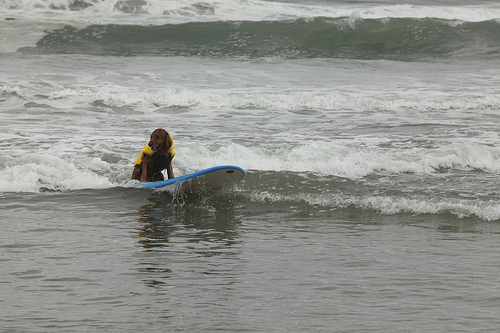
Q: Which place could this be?
A: It is an ocean.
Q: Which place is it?
A: It is an ocean.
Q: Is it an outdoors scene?
A: Yes, it is outdoors.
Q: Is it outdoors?
A: Yes, it is outdoors.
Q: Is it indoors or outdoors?
A: It is outdoors.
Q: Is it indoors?
A: No, it is outdoors.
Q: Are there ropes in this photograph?
A: No, there are no ropes.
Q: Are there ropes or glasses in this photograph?
A: No, there are no ropes or glasses.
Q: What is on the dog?
A: The life jacket is on the dog.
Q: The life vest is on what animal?
A: The life vest is on the dog.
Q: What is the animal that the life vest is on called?
A: The animal is a dog.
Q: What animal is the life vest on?
A: The life vest is on the dog.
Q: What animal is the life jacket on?
A: The life vest is on the dog.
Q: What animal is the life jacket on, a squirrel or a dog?
A: The life jacket is on a dog.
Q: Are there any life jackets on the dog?
A: Yes, there is a life jacket on the dog.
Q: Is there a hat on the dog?
A: No, there is a life jacket on the dog.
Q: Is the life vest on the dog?
A: Yes, the life vest is on the dog.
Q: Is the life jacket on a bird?
A: No, the life jacket is on the dog.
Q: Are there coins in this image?
A: No, there are no coins.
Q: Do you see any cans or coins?
A: No, there are no coins or cans.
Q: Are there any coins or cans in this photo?
A: No, there are no coins or cans.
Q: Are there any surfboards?
A: Yes, there is a surfboard.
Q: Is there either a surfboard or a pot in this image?
A: Yes, there is a surfboard.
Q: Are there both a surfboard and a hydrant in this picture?
A: No, there is a surfboard but no fire hydrants.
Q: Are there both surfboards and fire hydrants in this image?
A: No, there is a surfboard but no fire hydrants.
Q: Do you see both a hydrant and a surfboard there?
A: No, there is a surfboard but no fire hydrants.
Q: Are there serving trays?
A: No, there are no serving trays.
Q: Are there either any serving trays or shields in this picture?
A: No, there are no serving trays or shields.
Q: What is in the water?
A: The surf board is in the water.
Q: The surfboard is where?
A: The surfboard is in the water.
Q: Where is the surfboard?
A: The surfboard is in the water.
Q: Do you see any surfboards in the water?
A: Yes, there is a surfboard in the water.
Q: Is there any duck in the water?
A: No, there is a surfboard in the water.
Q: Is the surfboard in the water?
A: Yes, the surfboard is in the water.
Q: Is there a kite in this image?
A: No, there are no kites.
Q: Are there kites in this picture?
A: No, there are no kites.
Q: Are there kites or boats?
A: No, there are no kites or boats.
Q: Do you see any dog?
A: Yes, there is a dog.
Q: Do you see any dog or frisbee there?
A: Yes, there is a dog.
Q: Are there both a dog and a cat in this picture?
A: No, there is a dog but no cats.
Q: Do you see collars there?
A: No, there are no collars.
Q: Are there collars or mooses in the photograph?
A: No, there are no collars or mooses.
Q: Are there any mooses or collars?
A: No, there are no collars or mooses.